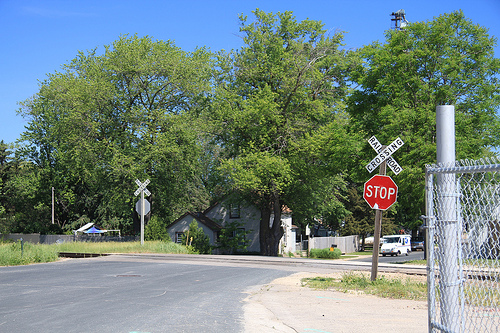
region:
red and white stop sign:
[349, 169, 416, 224]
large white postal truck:
[376, 226, 411, 260]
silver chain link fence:
[427, 169, 484, 263]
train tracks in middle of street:
[131, 243, 300, 268]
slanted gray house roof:
[180, 205, 231, 241]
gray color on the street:
[83, 268, 192, 307]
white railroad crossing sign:
[362, 120, 419, 184]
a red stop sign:
[357, 161, 400, 216]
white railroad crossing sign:
[126, 163, 155, 199]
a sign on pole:
[366, 154, 391, 279]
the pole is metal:
[357, 130, 404, 277]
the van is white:
[377, 220, 410, 262]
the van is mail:
[380, 220, 412, 266]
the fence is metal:
[423, 155, 494, 329]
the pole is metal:
[429, 98, 475, 330]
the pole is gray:
[430, 104, 462, 331]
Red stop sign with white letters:
[363, 172, 399, 209]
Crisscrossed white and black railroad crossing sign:
[365, 133, 405, 175]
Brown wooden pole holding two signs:
[366, 141, 386, 281]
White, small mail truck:
[377, 232, 412, 257]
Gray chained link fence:
[421, 101, 496, 327]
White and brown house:
[202, 181, 292, 253]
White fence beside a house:
[305, 232, 356, 253]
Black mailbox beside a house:
[325, 240, 337, 250]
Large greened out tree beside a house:
[210, 5, 360, 256]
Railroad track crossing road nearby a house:
[50, 242, 495, 277]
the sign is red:
[362, 171, 397, 211]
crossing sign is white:
[364, 134, 403, 174]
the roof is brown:
[249, 185, 295, 215]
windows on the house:
[226, 204, 242, 224]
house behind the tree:
[184, 167, 304, 247]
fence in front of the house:
[171, 190, 360, 252]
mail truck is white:
[377, 234, 412, 260]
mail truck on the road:
[373, 229, 413, 259]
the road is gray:
[17, 254, 259, 330]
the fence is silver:
[421, 159, 498, 316]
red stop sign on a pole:
[361, 175, 401, 212]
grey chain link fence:
[415, 114, 498, 317]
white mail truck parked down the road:
[380, 230, 411, 257]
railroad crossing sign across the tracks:
[124, 172, 164, 244]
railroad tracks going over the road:
[118, 240, 368, 286]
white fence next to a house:
[307, 236, 366, 258]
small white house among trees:
[175, 194, 295, 261]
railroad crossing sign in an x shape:
[367, 132, 404, 176]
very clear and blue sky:
[11, 7, 99, 53]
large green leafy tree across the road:
[212, 12, 357, 213]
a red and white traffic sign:
[363, 172, 396, 212]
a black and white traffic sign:
[368, 127, 403, 170]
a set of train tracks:
[88, 246, 365, 268]